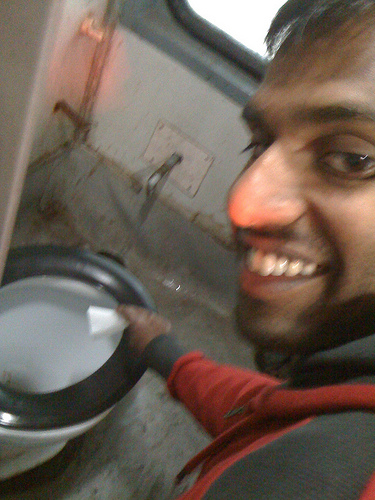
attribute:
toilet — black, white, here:
[2, 255, 140, 406]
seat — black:
[45, 255, 96, 276]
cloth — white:
[91, 311, 108, 326]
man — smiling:
[215, 5, 374, 495]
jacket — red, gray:
[215, 383, 344, 491]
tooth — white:
[293, 263, 296, 274]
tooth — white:
[265, 260, 271, 276]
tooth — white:
[248, 255, 252, 268]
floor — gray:
[118, 433, 172, 490]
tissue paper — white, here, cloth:
[93, 310, 116, 326]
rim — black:
[222, 41, 239, 55]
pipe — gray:
[148, 177, 160, 186]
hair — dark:
[287, 5, 301, 14]